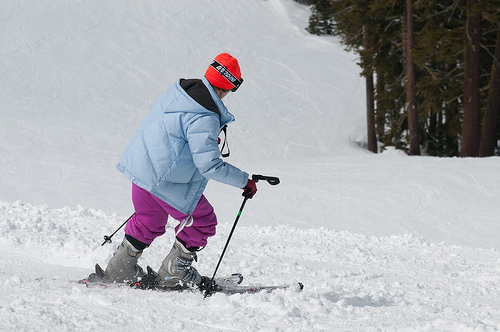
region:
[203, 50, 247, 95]
THE WOMAN IS WEARING A HAT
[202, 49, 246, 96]
THE WOMAN'S HAT IS RED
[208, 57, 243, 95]
THE WOMAN IS WEARING GOGGLES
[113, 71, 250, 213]
THE WOMAN IS WEARING A JACKET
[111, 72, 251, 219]
THE WOMAN'S JACKET IS BLUE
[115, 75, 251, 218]
THE WOMAN'S JACKET HAS A HOOD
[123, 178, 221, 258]
THE WOMAN IS WEARING SKI PANTS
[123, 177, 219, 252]
THE WOMAN'S PANTS ARE PURPLE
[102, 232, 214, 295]
THE WOMAN IS WEARING SKI BOOTS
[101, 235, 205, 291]
THE WOMAN'S BOOTS ARE GREY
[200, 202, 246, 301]
part of a hooker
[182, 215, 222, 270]
part of a trouser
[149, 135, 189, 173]
part of a jacket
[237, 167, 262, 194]
part of a glove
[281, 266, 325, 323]
part of a skate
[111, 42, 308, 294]
a person skiing down a hill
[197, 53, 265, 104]
a person wearing a orange hat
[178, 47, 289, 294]
a person holding a ski pole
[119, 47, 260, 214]
a person wearing a blue jacket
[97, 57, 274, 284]
a person wearing purple pants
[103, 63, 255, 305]
a person wearing ski boots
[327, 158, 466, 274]
tracks in the snow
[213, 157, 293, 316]
a ski pole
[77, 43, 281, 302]
a person skiing in the snow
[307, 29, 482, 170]
several trees in the snow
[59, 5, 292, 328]
a person in the snow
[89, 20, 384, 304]
a person wearing a beanie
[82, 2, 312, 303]
a person wearing a jacket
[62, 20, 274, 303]
a person wearing an orange beanie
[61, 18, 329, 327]
a person wearing a blue jacket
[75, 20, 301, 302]
a person wearing pants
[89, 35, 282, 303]
a person on the snow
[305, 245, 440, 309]
snow covered ground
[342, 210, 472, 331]
ground covered in snow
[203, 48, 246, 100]
the head of a person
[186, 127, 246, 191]
the arm of a person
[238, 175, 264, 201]
the hand of a person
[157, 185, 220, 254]
the leg of a person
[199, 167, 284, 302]
a black ski pole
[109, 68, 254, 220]
a blue and black coat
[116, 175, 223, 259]
a pair of purple pants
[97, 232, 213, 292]
a pair of gray ski boots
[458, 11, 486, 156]
a brown tree trunk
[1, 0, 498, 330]
white snow on the ground